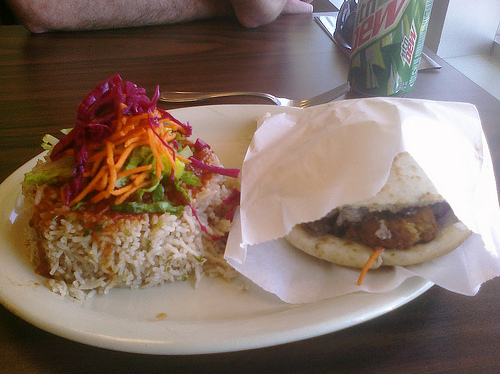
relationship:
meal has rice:
[47, 106, 157, 201] [25, 207, 225, 321]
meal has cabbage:
[23, 73, 243, 303] [46, 71, 192, 151]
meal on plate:
[23, 73, 478, 297] [0, 101, 435, 355]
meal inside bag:
[286, 149, 468, 269] [222, 94, 483, 304]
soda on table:
[347, 0, 434, 97] [0, 7, 495, 368]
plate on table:
[0, 101, 435, 355] [0, 7, 495, 368]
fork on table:
[156, 80, 354, 102] [0, 7, 495, 368]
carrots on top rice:
[68, 106, 191, 214] [22, 125, 248, 296]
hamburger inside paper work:
[284, 154, 470, 273] [222, 94, 497, 302]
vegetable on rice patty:
[64, 103, 186, 204] [22, 174, 241, 295]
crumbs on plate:
[158, 312, 168, 321] [0, 101, 435, 355]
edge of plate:
[66, 326, 172, 351] [0, 101, 435, 355]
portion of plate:
[176, 301, 261, 352] [0, 101, 435, 355]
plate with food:
[0, 101, 435, 355] [17, 70, 476, 303]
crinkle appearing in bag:
[366, 96, 407, 156] [222, 94, 483, 304]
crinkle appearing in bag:
[328, 103, 346, 123] [222, 94, 483, 304]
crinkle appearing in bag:
[392, 96, 442, 121] [222, 94, 483, 304]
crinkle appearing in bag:
[276, 195, 296, 237] [222, 94, 483, 304]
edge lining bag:
[223, 150, 480, 266] [222, 94, 483, 304]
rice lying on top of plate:
[21, 145, 251, 303] [0, 101, 435, 355]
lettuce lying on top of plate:
[22, 124, 202, 216] [0, 101, 435, 355]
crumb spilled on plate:
[148, 310, 167, 322] [0, 101, 435, 355]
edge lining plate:
[66, 326, 343, 361] [0, 101, 435, 355]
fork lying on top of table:
[156, 80, 349, 103] [0, 7, 495, 368]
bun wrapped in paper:
[284, 154, 473, 271] [222, 93, 483, 303]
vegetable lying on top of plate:
[49, 70, 239, 241] [0, 101, 435, 355]